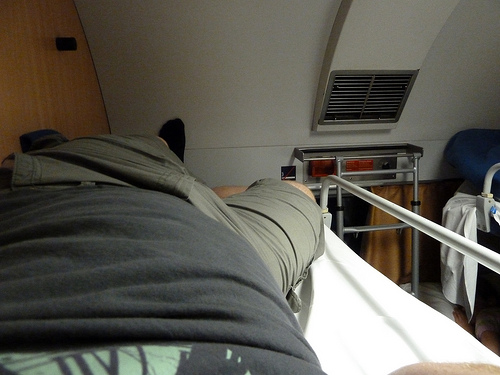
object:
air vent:
[318, 70, 421, 126]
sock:
[157, 117, 187, 164]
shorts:
[0, 133, 328, 315]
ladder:
[289, 143, 421, 302]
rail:
[320, 174, 499, 335]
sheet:
[289, 221, 499, 375]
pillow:
[444, 128, 500, 197]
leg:
[206, 177, 338, 276]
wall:
[72, 0, 500, 181]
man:
[1, 119, 500, 375]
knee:
[280, 180, 316, 203]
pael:
[0, 0, 116, 160]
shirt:
[0, 185, 337, 375]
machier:
[309, 148, 398, 183]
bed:
[0, 175, 500, 374]